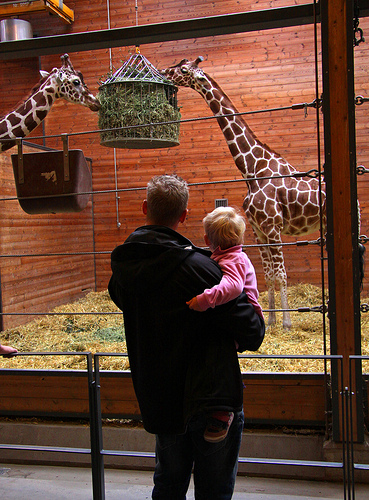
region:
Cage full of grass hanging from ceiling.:
[98, 53, 180, 147]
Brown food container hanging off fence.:
[11, 131, 90, 214]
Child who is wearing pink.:
[188, 205, 262, 441]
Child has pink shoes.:
[203, 412, 233, 442]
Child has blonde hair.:
[203, 205, 245, 245]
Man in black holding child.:
[114, 175, 266, 499]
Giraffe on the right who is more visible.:
[162, 55, 363, 327]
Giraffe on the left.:
[0, 53, 100, 150]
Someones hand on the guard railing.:
[1, 343, 18, 358]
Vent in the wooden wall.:
[214, 198, 228, 206]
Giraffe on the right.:
[157, 56, 358, 330]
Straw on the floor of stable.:
[5, 288, 367, 368]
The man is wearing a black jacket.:
[107, 225, 264, 432]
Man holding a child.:
[108, 177, 265, 498]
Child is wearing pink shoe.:
[203, 408, 234, 439]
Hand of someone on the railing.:
[1, 343, 17, 355]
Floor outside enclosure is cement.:
[0, 463, 367, 499]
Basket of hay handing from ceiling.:
[99, 51, 180, 145]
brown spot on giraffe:
[204, 90, 212, 101]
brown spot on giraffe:
[219, 97, 231, 109]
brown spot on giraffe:
[221, 125, 233, 139]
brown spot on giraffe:
[230, 123, 242, 134]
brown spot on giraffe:
[227, 141, 241, 157]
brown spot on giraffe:
[243, 127, 255, 145]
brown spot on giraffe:
[252, 188, 266, 209]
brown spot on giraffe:
[255, 157, 267, 173]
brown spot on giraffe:
[269, 173, 283, 186]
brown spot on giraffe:
[261, 184, 275, 196]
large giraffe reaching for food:
[162, 50, 330, 334]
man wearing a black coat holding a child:
[108, 171, 260, 498]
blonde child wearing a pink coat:
[183, 199, 272, 350]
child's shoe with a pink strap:
[199, 406, 234, 445]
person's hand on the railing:
[0, 342, 21, 361]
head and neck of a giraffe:
[0, 51, 103, 149]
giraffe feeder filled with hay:
[93, 44, 182, 149]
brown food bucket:
[7, 132, 95, 216]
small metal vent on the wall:
[213, 196, 230, 207]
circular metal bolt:
[289, 95, 323, 111]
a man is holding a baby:
[104, 174, 267, 439]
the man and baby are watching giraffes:
[36, 47, 262, 263]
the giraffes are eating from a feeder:
[16, 9, 359, 169]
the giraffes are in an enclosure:
[10, 7, 357, 486]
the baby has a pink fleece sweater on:
[190, 203, 270, 353]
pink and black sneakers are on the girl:
[201, 403, 236, 442]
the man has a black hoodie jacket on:
[108, 224, 264, 406]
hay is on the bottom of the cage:
[14, 280, 364, 369]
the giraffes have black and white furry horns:
[52, 50, 208, 78]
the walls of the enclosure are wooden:
[20, 16, 364, 306]